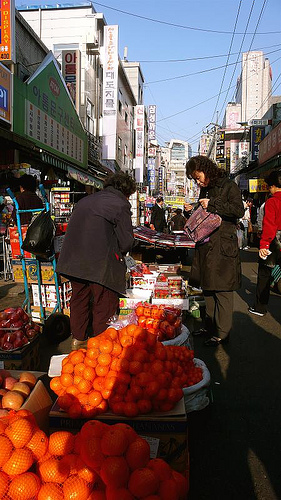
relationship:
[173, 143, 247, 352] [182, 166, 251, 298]
woman in coat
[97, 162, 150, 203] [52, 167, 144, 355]
head of person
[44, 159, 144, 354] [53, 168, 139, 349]
arm of woman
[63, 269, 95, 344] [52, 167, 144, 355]
leg of person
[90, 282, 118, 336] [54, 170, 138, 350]
leg belonging to person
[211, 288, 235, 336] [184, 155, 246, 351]
leg belonging to woman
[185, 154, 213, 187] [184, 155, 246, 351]
head belonging to woman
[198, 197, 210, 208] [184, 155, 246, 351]
hand belonging to woman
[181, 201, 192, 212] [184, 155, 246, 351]
hand belonging to woman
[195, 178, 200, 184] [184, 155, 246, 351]
nose belonging to woman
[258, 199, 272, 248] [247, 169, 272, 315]
arm belonging to person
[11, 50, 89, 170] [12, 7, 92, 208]
sign attached to building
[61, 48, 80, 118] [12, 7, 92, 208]
sign attached to building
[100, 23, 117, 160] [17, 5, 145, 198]
sign attached to building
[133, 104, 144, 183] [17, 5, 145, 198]
sign attached to building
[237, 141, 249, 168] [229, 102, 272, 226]
sign attached to building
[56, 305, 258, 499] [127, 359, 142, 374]
shadow casted on orange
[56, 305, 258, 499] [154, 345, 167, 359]
shadow casted on orange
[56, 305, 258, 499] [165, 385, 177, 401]
shadow casted on orange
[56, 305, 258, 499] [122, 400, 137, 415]
shadow casted on orange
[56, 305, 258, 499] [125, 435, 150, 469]
shadow casted on orange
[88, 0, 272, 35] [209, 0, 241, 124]
wire crossing wire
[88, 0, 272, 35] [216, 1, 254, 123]
wire crossing wire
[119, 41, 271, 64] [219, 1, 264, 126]
wire crossing wire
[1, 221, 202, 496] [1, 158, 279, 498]
food displayed at market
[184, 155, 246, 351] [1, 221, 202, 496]
woman shopping for food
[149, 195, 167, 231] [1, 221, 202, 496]
person shopping for food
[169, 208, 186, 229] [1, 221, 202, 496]
person shopping for food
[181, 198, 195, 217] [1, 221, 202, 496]
person shopping for food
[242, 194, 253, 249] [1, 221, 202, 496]
person shopping for food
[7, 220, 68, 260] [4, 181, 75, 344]
box sitting on top of cart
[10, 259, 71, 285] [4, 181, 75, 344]
box sitting on top of cart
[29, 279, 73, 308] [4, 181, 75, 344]
box sitting on top of cart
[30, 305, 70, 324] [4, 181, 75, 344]
box sitting on top of cart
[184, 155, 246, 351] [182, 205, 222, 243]
woman holding purse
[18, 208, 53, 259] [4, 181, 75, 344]
bag hanging from cart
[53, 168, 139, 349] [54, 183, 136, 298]
woman wearing coat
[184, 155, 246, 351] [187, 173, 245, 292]
woman wearing coat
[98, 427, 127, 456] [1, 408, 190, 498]
orange lying in bundle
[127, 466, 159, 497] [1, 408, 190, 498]
orange lying in bundle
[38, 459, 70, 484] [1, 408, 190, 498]
orange lying in bundle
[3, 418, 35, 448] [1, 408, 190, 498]
orange lying in bundle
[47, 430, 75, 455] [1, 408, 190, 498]
orange lying in bundle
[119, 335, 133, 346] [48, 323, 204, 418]
orange lying in bundle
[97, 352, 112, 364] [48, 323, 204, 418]
orange lying in bundle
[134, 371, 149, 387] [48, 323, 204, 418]
orange lying in bundle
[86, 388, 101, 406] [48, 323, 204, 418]
orange lying in bundle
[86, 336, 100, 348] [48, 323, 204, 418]
orange lying in bundle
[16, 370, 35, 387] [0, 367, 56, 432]
apple lying inside box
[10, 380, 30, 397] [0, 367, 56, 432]
apple lying inside box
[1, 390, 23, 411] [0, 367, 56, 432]
apple lying inside box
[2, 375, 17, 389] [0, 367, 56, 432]
apple lying inside box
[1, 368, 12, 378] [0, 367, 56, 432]
apple lying inside box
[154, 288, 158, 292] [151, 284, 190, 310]
strawberry lying inside box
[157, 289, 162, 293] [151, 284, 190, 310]
strawberry lying inside box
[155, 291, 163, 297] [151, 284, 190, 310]
strawberry lying inside box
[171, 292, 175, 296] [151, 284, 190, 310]
strawberry lying inside box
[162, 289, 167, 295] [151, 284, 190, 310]
strawberry lying inside box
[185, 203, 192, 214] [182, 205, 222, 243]
hand holding purse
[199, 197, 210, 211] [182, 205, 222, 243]
hand holding purse